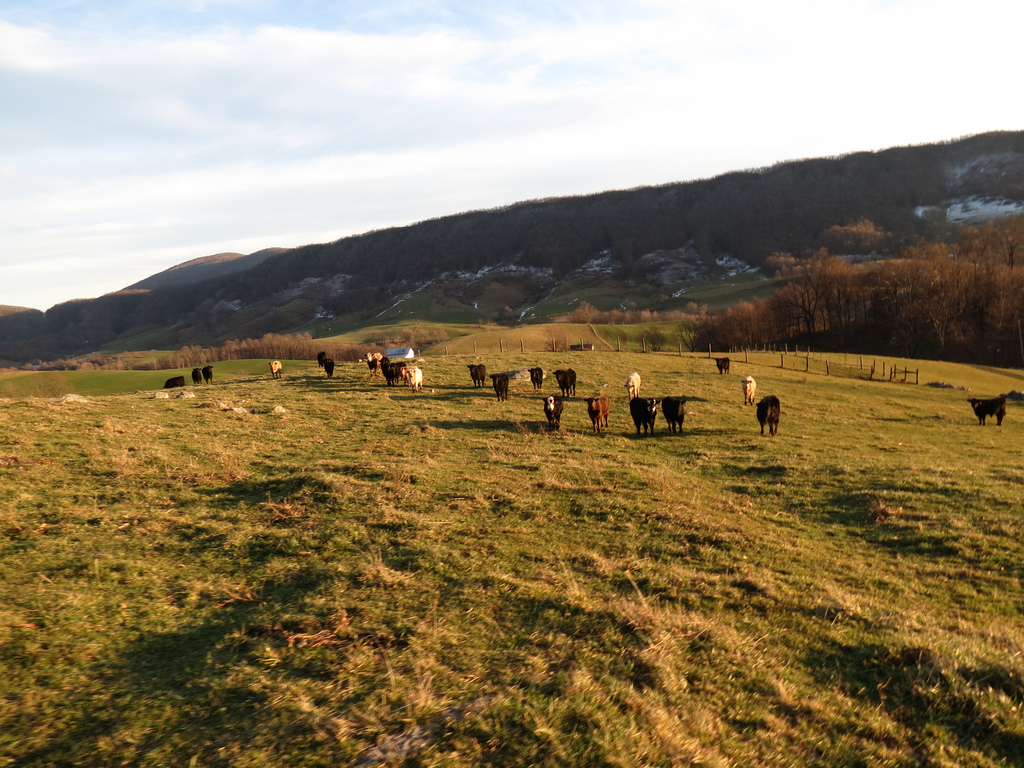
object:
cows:
[528, 367, 662, 438]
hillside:
[636, 351, 679, 373]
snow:
[517, 265, 547, 278]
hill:
[504, 189, 635, 305]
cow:
[400, 366, 424, 394]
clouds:
[359, 43, 454, 123]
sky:
[165, 11, 193, 24]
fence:
[745, 341, 800, 371]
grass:
[262, 469, 333, 500]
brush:
[224, 338, 256, 360]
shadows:
[238, 477, 317, 518]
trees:
[410, 289, 479, 323]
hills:
[347, 215, 443, 326]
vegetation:
[430, 298, 498, 338]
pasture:
[304, 393, 362, 419]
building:
[384, 347, 414, 359]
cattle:
[378, 356, 424, 394]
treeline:
[492, 302, 527, 324]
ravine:
[372, 297, 404, 319]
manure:
[540, 434, 568, 453]